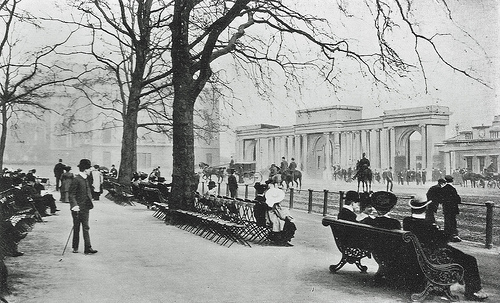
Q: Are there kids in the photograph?
A: No, there are no kids.